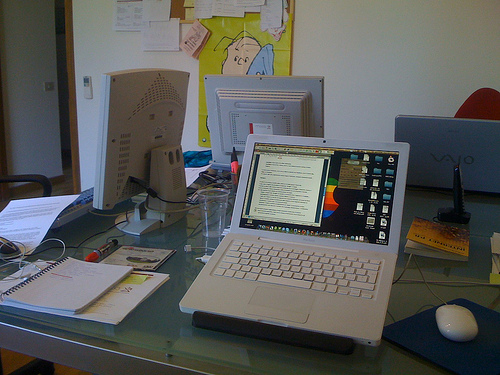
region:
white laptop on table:
[211, 134, 416, 373]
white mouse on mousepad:
[419, 295, 479, 348]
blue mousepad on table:
[377, 263, 487, 374]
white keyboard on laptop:
[220, 233, 400, 323]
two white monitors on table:
[90, 70, 330, 220]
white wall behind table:
[311, 29, 432, 112]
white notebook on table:
[35, 249, 127, 331]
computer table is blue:
[97, 238, 237, 358]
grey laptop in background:
[394, 116, 499, 189]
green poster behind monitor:
[200, 33, 282, 143]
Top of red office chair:
[450, 82, 497, 122]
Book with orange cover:
[401, 213, 473, 268]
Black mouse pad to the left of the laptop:
[378, 293, 499, 373]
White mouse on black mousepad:
[432, 299, 482, 346]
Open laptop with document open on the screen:
[174, 128, 413, 349]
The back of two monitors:
[90, 64, 328, 238]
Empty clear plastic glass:
[193, 183, 233, 243]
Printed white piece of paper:
[0, 189, 82, 265]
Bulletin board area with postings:
[109, 0, 301, 155]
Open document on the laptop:
[240, 144, 336, 229]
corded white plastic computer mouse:
[386, 303, 476, 338]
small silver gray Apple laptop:
[180, 131, 410, 343]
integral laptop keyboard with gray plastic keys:
[210, 236, 377, 296]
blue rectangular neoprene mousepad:
[381, 296, 497, 371]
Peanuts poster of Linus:
[196, 1, 291, 146]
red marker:
[85, 240, 115, 260]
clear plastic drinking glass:
[196, 187, 226, 237]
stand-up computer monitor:
[92, 67, 188, 233]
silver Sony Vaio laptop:
[395, 115, 498, 191]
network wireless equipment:
[436, 166, 471, 223]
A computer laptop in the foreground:
[178, 115, 416, 350]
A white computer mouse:
[422, 298, 488, 348]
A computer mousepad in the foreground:
[383, 281, 498, 373]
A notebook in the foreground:
[0, 246, 142, 326]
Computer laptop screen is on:
[226, 128, 406, 252]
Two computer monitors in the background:
[84, 55, 346, 239]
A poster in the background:
[192, 17, 297, 147]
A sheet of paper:
[3, 191, 81, 273]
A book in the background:
[403, 201, 480, 272]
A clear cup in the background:
[185, 178, 229, 250]